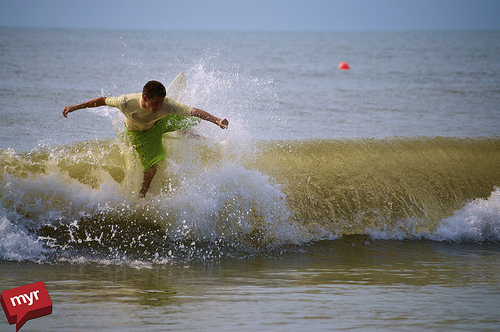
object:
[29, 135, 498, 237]
wave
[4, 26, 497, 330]
water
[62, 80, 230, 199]
man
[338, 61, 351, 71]
buoy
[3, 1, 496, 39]
sky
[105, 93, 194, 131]
shirt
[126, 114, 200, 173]
shorts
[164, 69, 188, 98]
surfboard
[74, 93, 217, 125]
arms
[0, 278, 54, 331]
logo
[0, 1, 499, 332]
picture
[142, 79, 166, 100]
hair